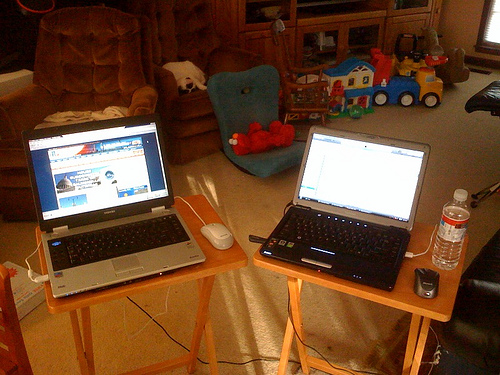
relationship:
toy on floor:
[325, 59, 448, 118] [1, 66, 500, 374]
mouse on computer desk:
[200, 219, 234, 250] [34, 193, 250, 374]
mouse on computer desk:
[413, 264, 440, 300] [251, 220, 472, 374]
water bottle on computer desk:
[429, 186, 476, 271] [251, 220, 472, 374]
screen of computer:
[27, 120, 176, 220] [20, 113, 210, 299]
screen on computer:
[297, 132, 430, 224] [257, 124, 435, 294]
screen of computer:
[297, 132, 430, 224] [257, 124, 435, 294]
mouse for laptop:
[200, 219, 234, 250] [20, 110, 213, 299]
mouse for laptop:
[413, 264, 440, 300] [256, 122, 434, 295]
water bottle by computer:
[429, 186, 476, 271] [257, 124, 435, 294]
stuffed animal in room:
[226, 117, 299, 161] [2, 0, 500, 374]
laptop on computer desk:
[20, 110, 213, 299] [34, 193, 250, 374]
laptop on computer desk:
[256, 122, 434, 295] [251, 220, 472, 374]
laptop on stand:
[20, 110, 213, 299] [33, 190, 253, 374]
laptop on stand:
[256, 122, 434, 295] [251, 218, 474, 374]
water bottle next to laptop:
[429, 186, 476, 271] [256, 122, 434, 295]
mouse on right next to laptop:
[413, 264, 440, 300] [256, 122, 434, 295]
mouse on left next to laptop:
[200, 219, 234, 250] [20, 110, 213, 299]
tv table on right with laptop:
[252, 213, 474, 374] [256, 122, 434, 295]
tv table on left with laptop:
[26, 188, 251, 374] [20, 110, 213, 299]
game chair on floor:
[206, 62, 311, 181] [1, 66, 500, 374]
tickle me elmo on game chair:
[228, 115, 297, 162] [206, 62, 311, 181]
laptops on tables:
[22, 107, 433, 303] [33, 189, 470, 373]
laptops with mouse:
[22, 107, 433, 303] [413, 264, 440, 300]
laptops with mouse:
[22, 107, 433, 303] [200, 219, 234, 250]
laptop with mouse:
[20, 110, 213, 299] [200, 219, 234, 250]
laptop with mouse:
[256, 122, 434, 295] [413, 264, 440, 300]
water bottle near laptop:
[429, 186, 476, 271] [256, 122, 434, 295]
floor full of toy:
[1, 66, 500, 374] [319, 45, 448, 120]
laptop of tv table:
[256, 122, 434, 295] [252, 213, 474, 374]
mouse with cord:
[200, 219, 234, 250] [175, 187, 208, 227]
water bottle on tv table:
[429, 186, 476, 271] [252, 213, 474, 374]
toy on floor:
[319, 45, 448, 120] [1, 66, 500, 374]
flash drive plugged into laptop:
[249, 232, 268, 247] [256, 122, 434, 295]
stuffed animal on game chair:
[226, 117, 299, 161] [206, 62, 311, 181]